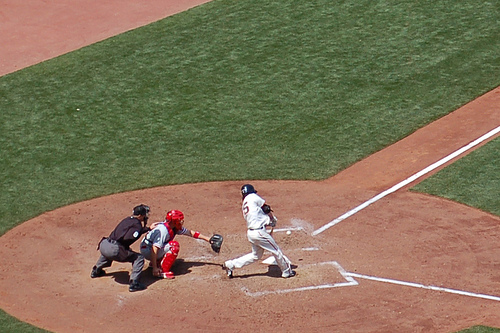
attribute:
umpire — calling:
[85, 199, 160, 300]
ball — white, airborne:
[284, 226, 292, 237]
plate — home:
[262, 250, 293, 268]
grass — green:
[1, 0, 500, 332]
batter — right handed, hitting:
[216, 178, 297, 281]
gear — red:
[163, 209, 182, 282]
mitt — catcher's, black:
[208, 232, 228, 255]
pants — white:
[221, 224, 295, 280]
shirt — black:
[102, 214, 150, 251]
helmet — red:
[163, 208, 185, 238]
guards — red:
[161, 240, 180, 274]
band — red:
[192, 230, 200, 241]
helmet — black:
[238, 181, 260, 197]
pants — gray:
[86, 236, 147, 285]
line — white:
[309, 120, 499, 236]